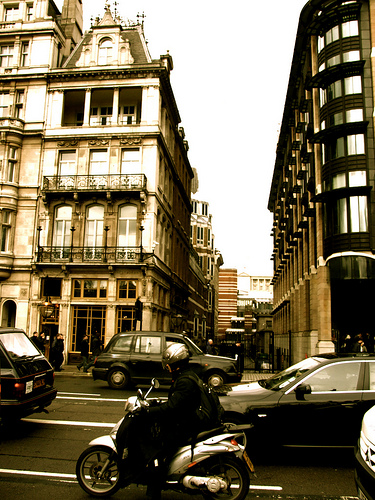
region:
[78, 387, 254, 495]
a silver motorcycle on street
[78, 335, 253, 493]
a person riding a motorcycle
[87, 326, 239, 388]
a parked black car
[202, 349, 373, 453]
a black car on street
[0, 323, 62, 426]
a black car on street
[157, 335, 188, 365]
a black protective helmet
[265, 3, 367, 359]
a tall building across street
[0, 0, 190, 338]
a tall building across street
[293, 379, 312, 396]
car driver side rear view mirror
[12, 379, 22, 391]
car red brake light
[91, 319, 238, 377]
black car on road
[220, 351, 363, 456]
black car on road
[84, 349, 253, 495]
person riding on motorcycle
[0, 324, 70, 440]
black car on road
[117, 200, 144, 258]
window on store front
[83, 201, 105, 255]
window on store front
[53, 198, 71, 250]
window on store front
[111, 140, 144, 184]
window on store front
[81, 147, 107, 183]
window on store front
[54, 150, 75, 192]
window on store front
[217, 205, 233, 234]
part of a cloud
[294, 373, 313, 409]
part of side mirror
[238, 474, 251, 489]
edge of a wheel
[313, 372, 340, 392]
part of a window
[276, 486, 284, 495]
edge of a line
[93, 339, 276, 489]
man riding a motor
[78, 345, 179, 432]
man riding a motor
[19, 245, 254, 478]
man riding a motor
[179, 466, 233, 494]
Driveline of the scooter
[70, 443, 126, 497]
Front wheel of the scooter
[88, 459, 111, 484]
Disc brake rotor on the front wheel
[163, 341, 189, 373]
Helmet worn by person riding a scooter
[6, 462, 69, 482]
White lines painted on the street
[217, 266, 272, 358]
Tall buildings down the alley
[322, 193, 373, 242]
Window on the corner of a building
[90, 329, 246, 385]
A car traveling through traffic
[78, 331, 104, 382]
Pedestrians on the sidewalk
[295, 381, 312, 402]
Rearview mirror on a black car